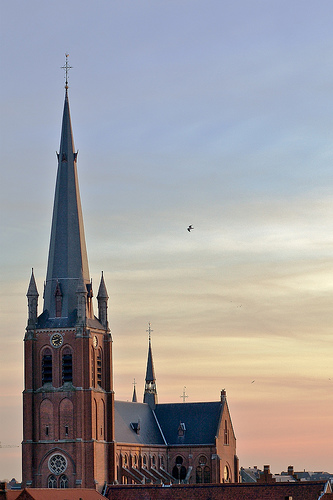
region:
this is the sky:
[164, 27, 248, 85]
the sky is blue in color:
[118, 132, 175, 180]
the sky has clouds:
[199, 270, 315, 372]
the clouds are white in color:
[220, 319, 313, 387]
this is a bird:
[181, 219, 199, 238]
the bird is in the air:
[181, 222, 196, 234]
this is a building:
[12, 44, 312, 493]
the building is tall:
[14, 6, 173, 434]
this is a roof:
[153, 405, 164, 409]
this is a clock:
[50, 333, 63, 345]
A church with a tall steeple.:
[4, 45, 236, 496]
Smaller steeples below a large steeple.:
[25, 266, 107, 326]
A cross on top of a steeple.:
[138, 319, 158, 400]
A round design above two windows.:
[44, 451, 67, 485]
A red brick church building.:
[22, 326, 238, 489]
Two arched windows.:
[35, 345, 74, 385]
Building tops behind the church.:
[236, 461, 329, 478]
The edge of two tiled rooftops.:
[0, 486, 101, 496]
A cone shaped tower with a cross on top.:
[41, 51, 93, 318]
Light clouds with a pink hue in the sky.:
[1, 185, 332, 482]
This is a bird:
[171, 207, 230, 325]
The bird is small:
[179, 214, 222, 314]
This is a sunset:
[134, 259, 287, 427]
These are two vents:
[7, 295, 103, 402]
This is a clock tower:
[47, 286, 143, 489]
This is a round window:
[44, 443, 87, 476]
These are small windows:
[39, 406, 114, 454]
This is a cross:
[147, 304, 218, 375]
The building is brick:
[40, 393, 80, 446]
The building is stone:
[45, 398, 122, 432]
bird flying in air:
[181, 223, 196, 234]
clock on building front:
[48, 330, 64, 353]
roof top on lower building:
[103, 477, 329, 499]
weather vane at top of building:
[54, 44, 78, 84]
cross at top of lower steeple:
[143, 322, 155, 341]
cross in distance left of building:
[130, 375, 137, 389]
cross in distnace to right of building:
[179, 388, 191, 401]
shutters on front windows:
[37, 343, 76, 392]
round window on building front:
[45, 450, 69, 477]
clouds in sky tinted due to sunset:
[0, 300, 332, 477]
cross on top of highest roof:
[57, 50, 76, 80]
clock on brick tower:
[47, 331, 63, 349]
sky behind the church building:
[3, 3, 325, 468]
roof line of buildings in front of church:
[5, 476, 332, 499]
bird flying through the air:
[185, 223, 193, 234]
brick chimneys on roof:
[255, 462, 300, 481]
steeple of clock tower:
[35, 86, 96, 321]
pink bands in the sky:
[6, 369, 325, 454]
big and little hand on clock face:
[51, 337, 58, 343]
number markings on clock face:
[50, 333, 63, 345]